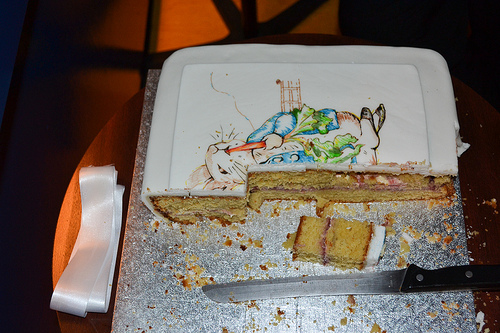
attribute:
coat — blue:
[246, 107, 358, 162]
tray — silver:
[111, 65, 478, 331]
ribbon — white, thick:
[52, 163, 129, 313]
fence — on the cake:
[268, 74, 308, 111]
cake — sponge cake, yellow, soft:
[162, 166, 457, 288]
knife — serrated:
[202, 266, 498, 305]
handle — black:
[401, 261, 498, 297]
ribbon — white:
[50, 164, 123, 315]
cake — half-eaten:
[126, 164, 476, 331]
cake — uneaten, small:
[271, 167, 404, 274]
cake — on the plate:
[151, 47, 476, 228]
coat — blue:
[249, 110, 326, 163]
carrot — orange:
[219, 140, 262, 151]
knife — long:
[200, 262, 497, 302]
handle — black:
[402, 261, 497, 290]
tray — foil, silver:
[111, 201, 480, 331]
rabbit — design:
[209, 93, 421, 201]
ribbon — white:
[51, 153, 122, 317]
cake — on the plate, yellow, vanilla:
[140, 40, 462, 227]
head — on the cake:
[163, 124, 292, 169]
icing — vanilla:
[172, 112, 244, 186]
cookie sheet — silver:
[108, 39, 484, 331]